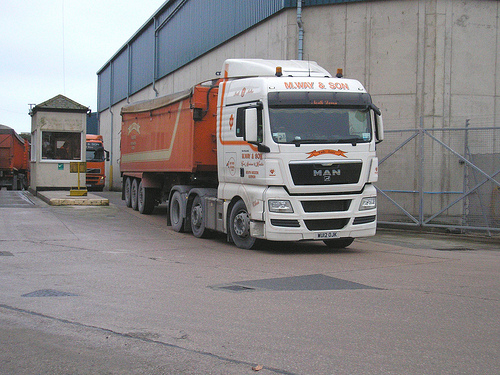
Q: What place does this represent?
A: It represents the parking lot.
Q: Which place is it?
A: It is a parking lot.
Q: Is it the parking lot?
A: Yes, it is the parking lot.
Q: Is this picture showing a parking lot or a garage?
A: It is showing a parking lot.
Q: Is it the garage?
A: No, it is the parking lot.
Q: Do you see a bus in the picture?
A: No, there are no buses.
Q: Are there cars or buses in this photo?
A: No, there are no buses or cars.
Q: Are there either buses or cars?
A: No, there are no buses or cars.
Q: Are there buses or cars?
A: No, there are no cars or buses.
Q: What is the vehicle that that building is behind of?
A: The vehicle is a truck.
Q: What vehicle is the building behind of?
A: The building is behind the truck.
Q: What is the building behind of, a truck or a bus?
A: The building is behind a truck.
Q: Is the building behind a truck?
A: Yes, the building is behind a truck.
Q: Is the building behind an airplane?
A: No, the building is behind a truck.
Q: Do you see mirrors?
A: Yes, there is a mirror.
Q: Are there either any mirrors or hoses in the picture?
A: Yes, there is a mirror.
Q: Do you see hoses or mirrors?
A: Yes, there is a mirror.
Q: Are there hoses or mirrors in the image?
A: Yes, there is a mirror.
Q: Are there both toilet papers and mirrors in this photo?
A: No, there is a mirror but no toilet papers.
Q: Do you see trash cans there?
A: No, there are no trash cans.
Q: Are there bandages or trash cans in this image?
A: No, there are no trash cans or bandages.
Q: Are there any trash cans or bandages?
A: No, there are no trash cans or bandages.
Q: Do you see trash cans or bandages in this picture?
A: No, there are no trash cans or bandages.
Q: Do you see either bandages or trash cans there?
A: No, there are no trash cans or bandages.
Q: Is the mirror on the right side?
A: Yes, the mirror is on the right of the image.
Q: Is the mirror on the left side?
A: No, the mirror is on the right of the image.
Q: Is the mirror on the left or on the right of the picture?
A: The mirror is on the right of the image.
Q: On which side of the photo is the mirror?
A: The mirror is on the right of the image.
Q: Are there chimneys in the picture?
A: No, there are no chimneys.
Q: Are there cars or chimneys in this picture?
A: No, there are no chimneys or cars.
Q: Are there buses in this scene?
A: No, there are no buses.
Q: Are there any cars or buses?
A: No, there are no buses or cars.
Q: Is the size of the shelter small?
A: Yes, the shelter is small.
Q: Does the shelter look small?
A: Yes, the shelter is small.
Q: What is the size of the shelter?
A: The shelter is small.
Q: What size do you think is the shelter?
A: The shelter is small.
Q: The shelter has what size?
A: The shelter is small.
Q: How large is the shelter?
A: The shelter is small.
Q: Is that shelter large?
A: No, the shelter is small.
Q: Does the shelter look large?
A: No, the shelter is small.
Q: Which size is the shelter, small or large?
A: The shelter is small.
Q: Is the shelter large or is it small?
A: The shelter is small.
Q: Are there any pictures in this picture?
A: No, there are no pictures.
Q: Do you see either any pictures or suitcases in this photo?
A: No, there are no pictures or suitcases.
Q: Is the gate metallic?
A: Yes, the gate is metallic.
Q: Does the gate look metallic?
A: Yes, the gate is metallic.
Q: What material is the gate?
A: The gate is made of metal.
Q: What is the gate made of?
A: The gate is made of metal.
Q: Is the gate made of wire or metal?
A: The gate is made of metal.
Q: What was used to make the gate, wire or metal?
A: The gate is made of metal.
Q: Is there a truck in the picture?
A: Yes, there is a truck.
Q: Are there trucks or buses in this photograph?
A: Yes, there is a truck.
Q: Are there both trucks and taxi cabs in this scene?
A: No, there is a truck but no taxis.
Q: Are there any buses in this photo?
A: No, there are no buses.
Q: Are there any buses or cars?
A: No, there are no buses or cars.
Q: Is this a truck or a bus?
A: This is a truck.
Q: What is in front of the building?
A: The truck is in front of the building.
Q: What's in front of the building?
A: The truck is in front of the building.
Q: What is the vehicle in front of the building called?
A: The vehicle is a truck.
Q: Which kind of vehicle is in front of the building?
A: The vehicle is a truck.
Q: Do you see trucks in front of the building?
A: Yes, there is a truck in front of the building.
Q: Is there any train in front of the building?
A: No, there is a truck in front of the building.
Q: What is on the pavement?
A: The truck is on the pavement.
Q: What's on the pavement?
A: The truck is on the pavement.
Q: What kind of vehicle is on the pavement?
A: The vehicle is a truck.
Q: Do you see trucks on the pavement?
A: Yes, there is a truck on the pavement.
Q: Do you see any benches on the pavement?
A: No, there is a truck on the pavement.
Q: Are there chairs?
A: No, there are no chairs.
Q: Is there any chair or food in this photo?
A: No, there are no chairs or food.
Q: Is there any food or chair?
A: No, there are no chairs or food.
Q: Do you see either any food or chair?
A: No, there are no chairs or food.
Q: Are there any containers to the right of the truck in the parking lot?
A: Yes, there is a container to the right of the truck.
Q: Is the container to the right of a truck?
A: Yes, the container is to the right of a truck.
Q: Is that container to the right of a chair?
A: No, the container is to the right of a truck.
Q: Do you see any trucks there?
A: Yes, there is a truck.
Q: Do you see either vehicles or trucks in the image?
A: Yes, there is a truck.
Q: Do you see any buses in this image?
A: No, there are no buses.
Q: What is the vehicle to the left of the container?
A: The vehicle is a truck.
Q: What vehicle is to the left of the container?
A: The vehicle is a truck.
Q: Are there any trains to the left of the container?
A: No, there is a truck to the left of the container.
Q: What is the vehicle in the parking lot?
A: The vehicle is a truck.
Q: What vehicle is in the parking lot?
A: The vehicle is a truck.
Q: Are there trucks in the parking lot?
A: Yes, there is a truck in the parking lot.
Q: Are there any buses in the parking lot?
A: No, there is a truck in the parking lot.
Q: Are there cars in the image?
A: No, there are no cars.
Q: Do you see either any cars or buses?
A: No, there are no cars or buses.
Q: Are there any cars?
A: No, there are no cars.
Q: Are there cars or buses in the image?
A: No, there are no cars or buses.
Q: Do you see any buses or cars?
A: No, there are no cars or buses.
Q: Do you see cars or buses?
A: No, there are no cars or buses.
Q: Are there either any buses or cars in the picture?
A: No, there are no cars or buses.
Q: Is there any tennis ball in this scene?
A: No, there are no tennis balls.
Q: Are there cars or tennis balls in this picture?
A: No, there are no tennis balls or cars.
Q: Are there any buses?
A: No, there are no buses.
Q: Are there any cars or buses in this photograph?
A: No, there are no buses or cars.